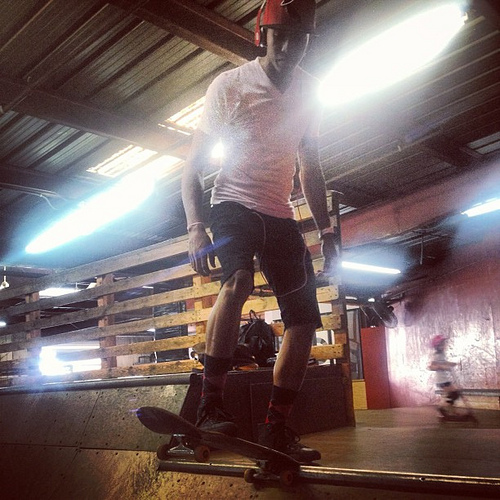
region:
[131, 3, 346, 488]
A person on a skateboard.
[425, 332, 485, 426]
Child on a scooter.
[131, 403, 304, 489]
A skateboard.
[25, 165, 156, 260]
Bright ceiling light.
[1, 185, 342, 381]
Wooden railing behind a man.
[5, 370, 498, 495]
Skateboard ramp in a building.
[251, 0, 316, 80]
Man wearing a red helmet.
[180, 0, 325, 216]
Man wearing white shirt.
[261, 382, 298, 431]
Black and red sock.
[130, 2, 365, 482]
A young man ready to skateboard on a ramp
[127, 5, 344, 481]
A young man ready to skateboard on a ramp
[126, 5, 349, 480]
A young man ready to skateboard on a ramp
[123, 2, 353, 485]
A young man ready to skateboard on a ramp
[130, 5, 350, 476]
A young man ready to skateboard on a ramp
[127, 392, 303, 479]
black skate board on side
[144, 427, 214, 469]
sturdy black wheels on skate board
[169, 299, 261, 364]
muscles in skater's leg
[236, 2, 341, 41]
red helmet on man's head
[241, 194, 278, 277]
white cord around man's waist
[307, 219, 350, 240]
white watch around man's wrist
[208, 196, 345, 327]
man wearing jeans shorts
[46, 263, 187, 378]
large wooden brown fence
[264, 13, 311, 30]
Person wearing hat on head.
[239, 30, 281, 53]
Person wearing headphones on head.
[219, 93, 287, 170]
Person wearing white shirt.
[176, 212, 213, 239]
White band around person's wrist.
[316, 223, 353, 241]
Person wearing white watch.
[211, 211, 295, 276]
Person wearing black shorts.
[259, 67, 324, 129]
Person's shirt is v-neck.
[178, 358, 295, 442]
Person wearing black and red socks.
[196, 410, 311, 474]
person wearing black shoes.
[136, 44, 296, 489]
a young man is on askteboard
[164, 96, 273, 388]
the boy is doing a hint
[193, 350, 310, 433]
socks are black and white incolor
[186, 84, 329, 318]
man is wearing a short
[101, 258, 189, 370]
the fence is made of wood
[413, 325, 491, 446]
man on sktae board at the backgrouend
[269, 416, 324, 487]
shoes are black incolor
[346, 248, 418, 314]
the lights areon